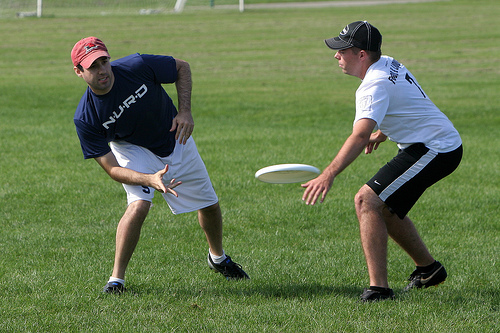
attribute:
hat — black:
[305, 14, 400, 64]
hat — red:
[67, 32, 112, 70]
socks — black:
[412, 261, 447, 272]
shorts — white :
[48, 20, 268, 322]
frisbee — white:
[253, 161, 319, 189]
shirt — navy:
[57, 52, 186, 163]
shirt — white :
[357, 55, 464, 153]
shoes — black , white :
[349, 262, 463, 301]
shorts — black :
[365, 135, 459, 212]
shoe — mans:
[200, 247, 255, 277]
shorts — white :
[326, 110, 453, 214]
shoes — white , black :
[361, 260, 451, 307]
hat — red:
[231, 0, 386, 58]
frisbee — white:
[251, 156, 323, 185]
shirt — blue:
[68, 53, 182, 156]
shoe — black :
[205, 251, 247, 278]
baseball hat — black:
[322, 13, 394, 60]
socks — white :
[95, 243, 227, 298]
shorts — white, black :
[365, 139, 463, 221]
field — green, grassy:
[0, 2, 498, 332]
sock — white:
[207, 246, 229, 266]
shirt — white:
[334, 56, 474, 166]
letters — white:
[85, 85, 155, 134]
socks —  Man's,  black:
[366, 284, 387, 294]